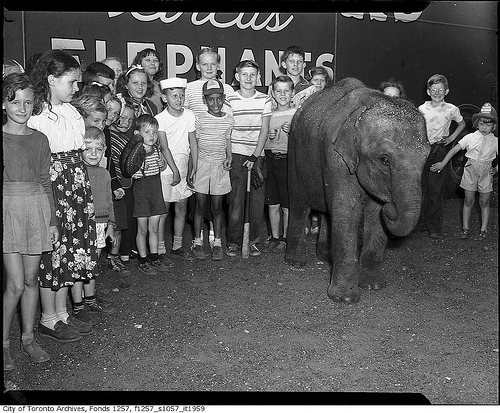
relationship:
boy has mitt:
[232, 59, 271, 253] [247, 157, 266, 187]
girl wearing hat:
[441, 93, 497, 239] [471, 98, 499, 117]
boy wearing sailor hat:
[156, 76, 203, 257] [159, 76, 190, 94]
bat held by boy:
[239, 160, 254, 259] [232, 59, 271, 253]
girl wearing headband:
[123, 62, 157, 117] [126, 65, 151, 82]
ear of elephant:
[340, 113, 362, 181] [285, 76, 429, 316]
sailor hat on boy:
[159, 76, 190, 94] [156, 76, 203, 257]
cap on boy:
[202, 77, 226, 100] [195, 78, 229, 265]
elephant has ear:
[285, 76, 429, 316] [340, 113, 362, 181]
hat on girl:
[471, 98, 499, 117] [441, 93, 497, 239]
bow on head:
[122, 61, 144, 78] [126, 62, 152, 107]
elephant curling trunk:
[285, 76, 429, 316] [387, 164, 421, 245]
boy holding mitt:
[232, 59, 271, 253] [247, 157, 266, 187]